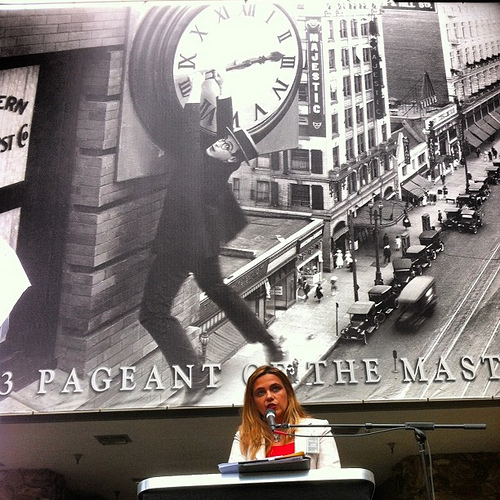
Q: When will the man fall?
A: Never.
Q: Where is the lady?
A: Bottom.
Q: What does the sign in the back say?
A: Majestic.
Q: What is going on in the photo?
A: Presentation.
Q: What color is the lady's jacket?
A: White.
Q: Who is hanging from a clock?
A: A man.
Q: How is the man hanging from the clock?
A: Holding.